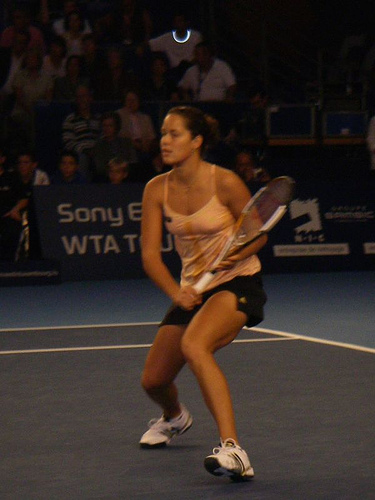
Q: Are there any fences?
A: No, there are no fences.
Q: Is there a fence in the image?
A: No, there are no fences.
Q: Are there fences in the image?
A: No, there are no fences.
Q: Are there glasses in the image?
A: No, there are no glasses.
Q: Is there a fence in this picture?
A: No, there are no fences.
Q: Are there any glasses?
A: No, there are no glasses.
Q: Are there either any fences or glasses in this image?
A: No, there are no glasses or fences.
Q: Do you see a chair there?
A: No, there are no chairs.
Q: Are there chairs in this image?
A: No, there are no chairs.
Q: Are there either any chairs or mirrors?
A: No, there are no chairs or mirrors.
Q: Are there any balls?
A: No, there are no balls.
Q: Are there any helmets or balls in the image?
A: No, there are no balls or helmets.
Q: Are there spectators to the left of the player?
A: Yes, there is a spectator to the left of the player.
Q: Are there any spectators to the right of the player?
A: No, the spectator is to the left of the player.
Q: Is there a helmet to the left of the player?
A: No, there is a spectator to the left of the player.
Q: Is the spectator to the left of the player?
A: Yes, the spectator is to the left of the player.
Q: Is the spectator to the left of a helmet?
A: No, the spectator is to the left of the player.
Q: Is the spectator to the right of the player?
A: No, the spectator is to the left of the player.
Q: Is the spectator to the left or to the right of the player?
A: The spectator is to the left of the player.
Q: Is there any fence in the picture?
A: No, there are no fences.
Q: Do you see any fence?
A: No, there are no fences.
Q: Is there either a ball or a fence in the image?
A: No, there are no fences or balls.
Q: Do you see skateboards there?
A: No, there are no skateboards.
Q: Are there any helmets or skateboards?
A: No, there are no skateboards or helmets.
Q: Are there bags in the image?
A: No, there are no bags.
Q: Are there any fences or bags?
A: No, there are no bags or fences.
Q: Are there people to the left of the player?
A: Yes, there are people to the left of the player.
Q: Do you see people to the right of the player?
A: No, the people are to the left of the player.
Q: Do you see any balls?
A: No, there are no balls.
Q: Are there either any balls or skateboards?
A: No, there are no balls or skateboards.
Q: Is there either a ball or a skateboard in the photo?
A: No, there are no balls or skateboards.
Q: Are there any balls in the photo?
A: No, there are no balls.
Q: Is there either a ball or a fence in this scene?
A: No, there are no balls or fences.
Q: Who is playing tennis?
A: The player is playing tennis.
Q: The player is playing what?
A: The player is playing tennis.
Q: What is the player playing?
A: The player is playing tennis.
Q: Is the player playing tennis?
A: Yes, the player is playing tennis.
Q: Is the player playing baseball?
A: No, the player is playing tennis.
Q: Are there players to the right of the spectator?
A: Yes, there is a player to the right of the spectator.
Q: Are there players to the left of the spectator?
A: No, the player is to the right of the spectator.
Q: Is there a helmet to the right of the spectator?
A: No, there is a player to the right of the spectator.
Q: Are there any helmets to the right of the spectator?
A: No, there is a player to the right of the spectator.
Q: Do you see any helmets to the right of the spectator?
A: No, there is a player to the right of the spectator.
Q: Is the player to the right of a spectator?
A: Yes, the player is to the right of a spectator.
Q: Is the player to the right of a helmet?
A: No, the player is to the right of a spectator.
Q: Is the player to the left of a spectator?
A: No, the player is to the right of a spectator.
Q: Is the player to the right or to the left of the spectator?
A: The player is to the right of the spectator.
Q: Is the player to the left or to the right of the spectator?
A: The player is to the right of the spectator.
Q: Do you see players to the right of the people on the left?
A: Yes, there is a player to the right of the people.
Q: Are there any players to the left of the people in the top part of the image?
A: No, the player is to the right of the people.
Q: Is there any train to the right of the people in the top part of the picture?
A: No, there is a player to the right of the people.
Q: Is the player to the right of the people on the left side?
A: Yes, the player is to the right of the people.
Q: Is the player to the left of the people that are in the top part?
A: No, the player is to the right of the people.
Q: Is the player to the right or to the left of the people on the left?
A: The player is to the right of the people.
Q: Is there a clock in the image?
A: No, there are no clocks.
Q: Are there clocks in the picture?
A: No, there are no clocks.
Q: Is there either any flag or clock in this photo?
A: No, there are no clocks or flags.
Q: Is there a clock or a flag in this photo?
A: No, there are no clocks or flags.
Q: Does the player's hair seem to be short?
A: Yes, the hair is short.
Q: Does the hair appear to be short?
A: Yes, the hair is short.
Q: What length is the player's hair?
A: The hair is short.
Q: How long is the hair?
A: The hair is short.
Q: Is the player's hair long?
A: No, the hair is short.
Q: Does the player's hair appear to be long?
A: No, the hair is short.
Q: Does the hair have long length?
A: No, the hair is short.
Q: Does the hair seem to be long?
A: No, the hair is short.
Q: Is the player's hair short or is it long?
A: The hair is short.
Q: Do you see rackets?
A: Yes, there is a racket.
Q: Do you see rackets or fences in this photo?
A: Yes, there is a racket.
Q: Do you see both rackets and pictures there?
A: No, there is a racket but no pictures.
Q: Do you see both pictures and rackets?
A: No, there is a racket but no pictures.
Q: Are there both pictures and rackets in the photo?
A: No, there is a racket but no pictures.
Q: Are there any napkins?
A: No, there are no napkins.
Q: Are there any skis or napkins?
A: No, there are no napkins or skis.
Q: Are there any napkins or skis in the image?
A: No, there are no napkins or skis.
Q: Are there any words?
A: Yes, there are words.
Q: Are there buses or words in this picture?
A: Yes, there are words.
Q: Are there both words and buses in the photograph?
A: No, there are words but no buses.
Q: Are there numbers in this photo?
A: No, there are no numbers.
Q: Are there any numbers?
A: No, there are no numbers.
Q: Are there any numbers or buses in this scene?
A: No, there are no numbers or buses.